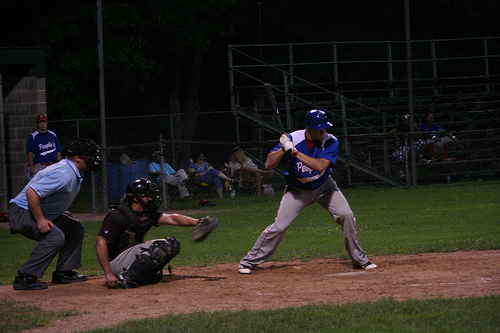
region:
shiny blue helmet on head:
[299, 100, 354, 140]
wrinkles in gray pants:
[331, 230, 390, 257]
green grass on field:
[325, 302, 426, 314]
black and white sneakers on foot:
[229, 259, 272, 280]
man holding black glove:
[187, 212, 217, 244]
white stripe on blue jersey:
[31, 142, 63, 157]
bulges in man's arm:
[158, 211, 186, 226]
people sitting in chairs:
[116, 130, 266, 187]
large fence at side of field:
[346, 119, 453, 190]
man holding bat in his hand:
[241, 90, 377, 258]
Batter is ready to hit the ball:
[220, 55, 457, 316]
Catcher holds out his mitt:
[174, 208, 253, 264]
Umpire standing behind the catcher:
[9, 110, 119, 299]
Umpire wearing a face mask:
[73, 126, 100, 163]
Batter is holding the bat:
[247, 70, 321, 211]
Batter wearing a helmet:
[292, 104, 336, 171]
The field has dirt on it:
[252, 260, 332, 331]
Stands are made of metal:
[340, 44, 494, 222]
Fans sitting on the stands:
[375, 83, 469, 183]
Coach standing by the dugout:
[22, 93, 85, 220]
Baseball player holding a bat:
[234, 76, 380, 278]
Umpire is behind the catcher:
[4, 132, 224, 294]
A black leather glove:
[182, 210, 221, 248]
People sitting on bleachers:
[389, 104, 462, 172]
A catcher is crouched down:
[91, 173, 222, 294]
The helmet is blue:
[297, 106, 335, 136]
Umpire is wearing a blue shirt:
[6, 133, 106, 219]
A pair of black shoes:
[8, 268, 89, 294]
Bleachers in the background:
[222, 31, 498, 187]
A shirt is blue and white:
[24, 127, 63, 167]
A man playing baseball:
[277, 45, 416, 322]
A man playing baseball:
[101, 176, 198, 272]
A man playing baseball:
[26, 152, 109, 277]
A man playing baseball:
[19, 108, 66, 152]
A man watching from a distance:
[144, 147, 191, 197]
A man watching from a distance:
[188, 151, 227, 197]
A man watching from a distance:
[224, 147, 259, 186]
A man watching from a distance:
[416, 105, 469, 163]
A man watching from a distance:
[384, 105, 423, 177]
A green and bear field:
[395, 177, 497, 294]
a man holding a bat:
[256, 73, 356, 155]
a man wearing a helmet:
[308, 112, 343, 140]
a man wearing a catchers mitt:
[192, 199, 225, 257]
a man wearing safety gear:
[109, 228, 177, 297]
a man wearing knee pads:
[125, 226, 181, 286]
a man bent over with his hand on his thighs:
[21, 127, 105, 248]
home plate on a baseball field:
[307, 251, 391, 301]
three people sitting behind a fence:
[132, 146, 272, 193]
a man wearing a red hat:
[29, 108, 63, 135]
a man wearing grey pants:
[261, 174, 365, 259]